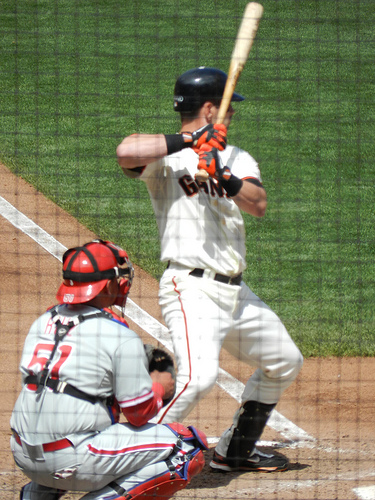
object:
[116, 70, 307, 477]
batter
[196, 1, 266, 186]
bat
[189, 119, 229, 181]
gloves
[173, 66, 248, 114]
helmet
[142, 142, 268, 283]
shirt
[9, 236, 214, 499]
catcher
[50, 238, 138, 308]
cap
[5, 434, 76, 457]
belt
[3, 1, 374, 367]
grass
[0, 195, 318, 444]
line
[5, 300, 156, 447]
shirt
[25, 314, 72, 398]
letters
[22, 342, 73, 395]
number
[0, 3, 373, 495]
field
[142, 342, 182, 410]
mitt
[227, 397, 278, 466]
shin guard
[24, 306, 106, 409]
straps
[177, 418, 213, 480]
knee guard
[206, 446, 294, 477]
cleats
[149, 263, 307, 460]
pants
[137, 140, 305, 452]
uniform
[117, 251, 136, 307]
mask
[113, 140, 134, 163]
elbow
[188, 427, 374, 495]
moud